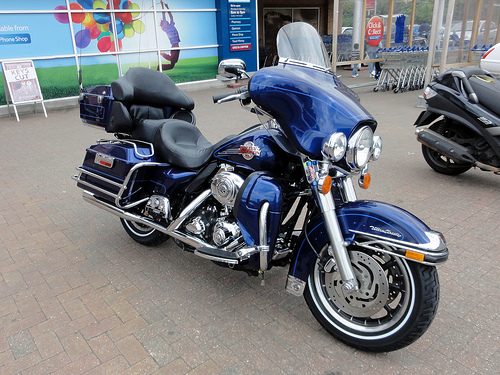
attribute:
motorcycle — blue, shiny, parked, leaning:
[73, 21, 449, 356]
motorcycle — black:
[414, 42, 500, 179]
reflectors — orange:
[320, 171, 426, 263]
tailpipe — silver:
[81, 189, 258, 260]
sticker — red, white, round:
[365, 15, 385, 48]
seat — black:
[106, 66, 237, 168]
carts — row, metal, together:
[370, 41, 496, 92]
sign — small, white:
[2, 59, 51, 123]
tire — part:
[304, 234, 440, 353]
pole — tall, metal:
[423, 0, 454, 91]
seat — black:
[471, 72, 499, 114]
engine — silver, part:
[181, 163, 250, 247]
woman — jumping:
[157, 2, 183, 74]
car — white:
[480, 42, 499, 78]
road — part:
[1, 69, 500, 373]